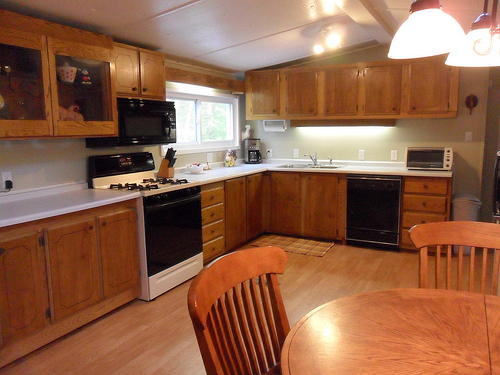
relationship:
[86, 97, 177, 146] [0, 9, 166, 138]
microwave in cabinets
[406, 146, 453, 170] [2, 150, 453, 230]
oven on counter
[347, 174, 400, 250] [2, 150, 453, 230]
dishwasher under counter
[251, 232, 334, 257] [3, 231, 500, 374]
rug on floor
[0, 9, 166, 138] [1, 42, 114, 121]
cabinets have windows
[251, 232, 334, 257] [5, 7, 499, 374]
rug in kitchen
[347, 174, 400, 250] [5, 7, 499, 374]
dishwasher in kitchen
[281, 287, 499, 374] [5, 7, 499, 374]
table in kitchen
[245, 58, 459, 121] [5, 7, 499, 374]
cabinets in kitchen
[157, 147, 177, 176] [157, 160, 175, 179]
knives in block